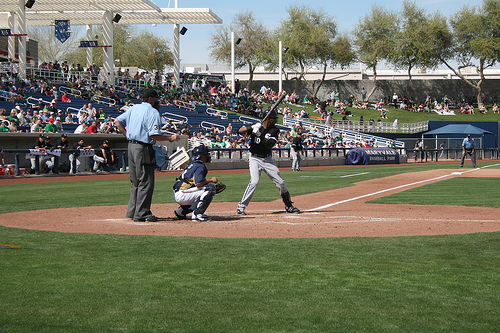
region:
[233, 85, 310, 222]
A baseball player is holding a bat.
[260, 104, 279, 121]
A baseball player is wearing a black helmet.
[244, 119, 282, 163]
A baseball player is wearing a black and white shirt.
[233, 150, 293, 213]
A baseball player is wearing white pants.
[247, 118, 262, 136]
A baseball player is wearing white gloves.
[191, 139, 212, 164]
A catcher is wearing a protective mask.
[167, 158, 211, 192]
A catcher is wearing a blue and white top.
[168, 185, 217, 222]
A catcher is wearing white pants.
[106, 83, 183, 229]
An umpire is standing behind a catcher.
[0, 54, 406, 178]
Spectators are in the stands.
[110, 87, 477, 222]
the people standing on the field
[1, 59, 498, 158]
the people in the audience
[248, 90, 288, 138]
the baseball bat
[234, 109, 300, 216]
the player holding the bat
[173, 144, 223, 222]
the catcher bending down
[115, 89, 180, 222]
the umpire standing up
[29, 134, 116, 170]
the players in the dug out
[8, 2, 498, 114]
the trees outside of the field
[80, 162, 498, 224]
the white lines on the field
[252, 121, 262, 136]
the two hands on the bat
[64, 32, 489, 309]
men playing baseball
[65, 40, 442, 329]
men on a baseball field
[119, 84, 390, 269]
men in uniform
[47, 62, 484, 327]
men in baseball uniform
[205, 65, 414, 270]
a man holding a bat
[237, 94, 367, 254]
a man swinging a bat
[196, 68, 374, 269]
a man wearing a black shirt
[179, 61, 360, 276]
a man wearing gloves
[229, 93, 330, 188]
a man wearing white gloves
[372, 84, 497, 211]
a blue tent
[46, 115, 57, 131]
spectator watch baseball game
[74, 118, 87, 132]
spectator watch baseball game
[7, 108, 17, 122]
spectator watch baseball game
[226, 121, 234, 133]
spectator watch baseball game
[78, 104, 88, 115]
spectator watch baseball game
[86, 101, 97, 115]
spectator watch baseball game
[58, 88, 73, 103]
spectator watch baseball game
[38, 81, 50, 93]
spectator watch baseball game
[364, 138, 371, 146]
spectator watch baseball game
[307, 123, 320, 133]
spectator watch baseball game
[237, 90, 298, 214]
Batter ready to swing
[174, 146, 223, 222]
Catcher is crouching down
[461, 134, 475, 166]
An umpire stands ready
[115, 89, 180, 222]
Umpire at home plate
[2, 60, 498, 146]
Crowd is watching the game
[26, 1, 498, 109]
A row of trees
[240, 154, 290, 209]
The pants are gray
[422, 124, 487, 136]
The tent is blue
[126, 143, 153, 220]
Pants are dark gray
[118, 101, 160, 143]
Shirt is light blue